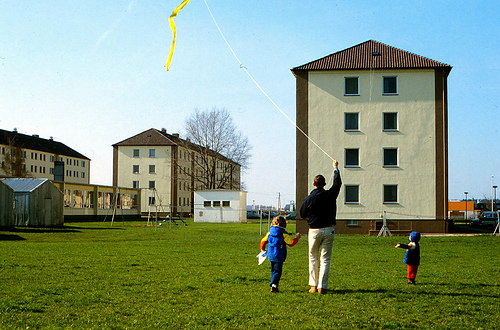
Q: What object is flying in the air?
A: A kite.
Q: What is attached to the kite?
A: A string.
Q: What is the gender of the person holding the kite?
A: Male.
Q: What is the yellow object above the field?
A: A kite.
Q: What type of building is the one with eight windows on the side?
A: An apartment.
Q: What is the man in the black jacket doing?
A: Flying a kite.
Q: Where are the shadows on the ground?
A: Behind the people.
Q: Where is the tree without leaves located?
A: On the left side of the house.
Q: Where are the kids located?
A: On the side of the man.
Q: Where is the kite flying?
A: In the air.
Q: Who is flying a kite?
A: The man.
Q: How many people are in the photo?
A: Three.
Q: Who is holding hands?
A: The man and the girl.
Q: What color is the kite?
A: Yellow.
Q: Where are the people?
A: In a field.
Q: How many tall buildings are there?
A: Three.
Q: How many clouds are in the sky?
A: None.